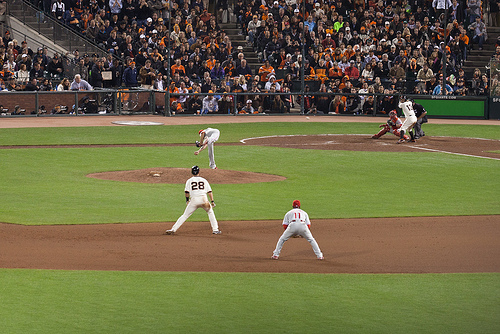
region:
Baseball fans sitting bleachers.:
[305, 12, 456, 100]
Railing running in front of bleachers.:
[52, 83, 387, 121]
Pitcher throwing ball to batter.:
[182, 123, 233, 170]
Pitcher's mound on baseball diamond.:
[89, 152, 286, 188]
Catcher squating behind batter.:
[368, 107, 405, 144]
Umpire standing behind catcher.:
[413, 98, 438, 138]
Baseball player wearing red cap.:
[283, 193, 312, 209]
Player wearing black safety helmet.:
[185, 162, 208, 177]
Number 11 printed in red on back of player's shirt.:
[286, 208, 306, 221]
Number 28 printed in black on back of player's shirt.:
[186, 176, 211, 194]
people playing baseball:
[3, 90, 487, 290]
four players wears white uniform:
[158, 92, 418, 260]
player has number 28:
[162, 152, 236, 245]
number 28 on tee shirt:
[183, 173, 212, 204]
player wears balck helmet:
[168, 161, 226, 238]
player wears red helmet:
[263, 192, 334, 274]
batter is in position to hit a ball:
[390, 87, 420, 142]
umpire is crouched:
[409, 92, 433, 140]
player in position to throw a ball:
[187, 124, 236, 171]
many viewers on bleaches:
[3, 0, 497, 115]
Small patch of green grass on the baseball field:
[205, 285, 221, 301]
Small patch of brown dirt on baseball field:
[351, 255, 361, 268]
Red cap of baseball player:
[293, 195, 302, 208]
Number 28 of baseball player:
[191, 175, 205, 191]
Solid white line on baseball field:
[446, 143, 458, 159]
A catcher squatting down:
[366, 110, 403, 140]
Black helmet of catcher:
[400, 91, 408, 101]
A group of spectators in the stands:
[331, 31, 375, 61]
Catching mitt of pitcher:
[193, 138, 203, 149]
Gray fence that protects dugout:
[31, 96, 43, 113]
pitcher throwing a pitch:
[175, 88, 248, 168]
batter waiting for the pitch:
[379, 93, 429, 150]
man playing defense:
[247, 153, 342, 280]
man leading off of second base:
[138, 161, 238, 256]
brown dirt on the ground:
[362, 223, 443, 259]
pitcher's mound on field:
[146, 148, 184, 193]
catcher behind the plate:
[366, 104, 405, 139]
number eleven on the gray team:
[264, 149, 340, 256]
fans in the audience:
[280, 34, 370, 87]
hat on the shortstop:
[286, 195, 304, 212]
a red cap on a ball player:
[290, 195, 301, 211]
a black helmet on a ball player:
[185, 165, 206, 177]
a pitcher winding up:
[190, 116, 235, 173]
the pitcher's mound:
[86, 154, 290, 187]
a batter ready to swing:
[394, 91, 418, 156]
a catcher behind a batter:
[369, 106, 400, 140]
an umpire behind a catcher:
[410, 98, 433, 147]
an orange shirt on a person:
[170, 63, 187, 76]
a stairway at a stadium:
[11, 3, 103, 57]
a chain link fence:
[165, 44, 390, 121]